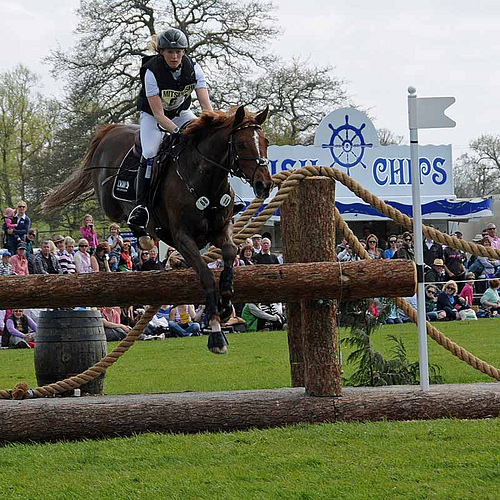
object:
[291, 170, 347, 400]
pole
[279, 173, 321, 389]
pole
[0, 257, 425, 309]
pole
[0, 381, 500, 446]
pole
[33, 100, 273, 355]
horse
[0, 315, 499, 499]
grass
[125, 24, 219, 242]
rider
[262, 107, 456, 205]
sign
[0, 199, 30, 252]
person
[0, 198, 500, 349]
crowd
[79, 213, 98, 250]
person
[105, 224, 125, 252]
person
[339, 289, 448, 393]
bush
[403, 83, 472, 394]
pole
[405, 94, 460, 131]
flag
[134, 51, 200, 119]
vest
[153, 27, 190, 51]
helmet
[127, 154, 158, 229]
boots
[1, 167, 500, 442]
fence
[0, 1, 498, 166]
clouds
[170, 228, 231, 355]
leg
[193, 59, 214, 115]
arm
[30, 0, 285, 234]
tree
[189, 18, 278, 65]
branch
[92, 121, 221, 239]
body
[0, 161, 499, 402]
rope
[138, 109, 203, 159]
pants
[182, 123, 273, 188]
bridle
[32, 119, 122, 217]
tail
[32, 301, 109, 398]
barrel